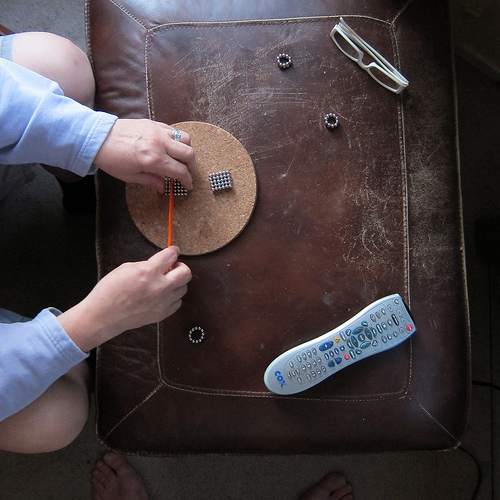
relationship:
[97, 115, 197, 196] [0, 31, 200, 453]
hand on person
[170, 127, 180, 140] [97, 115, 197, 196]
ring on hand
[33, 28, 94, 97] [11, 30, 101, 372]
knee on person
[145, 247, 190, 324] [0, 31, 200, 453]
fingers on person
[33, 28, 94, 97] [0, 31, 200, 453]
knee on person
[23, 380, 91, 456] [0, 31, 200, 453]
knee on person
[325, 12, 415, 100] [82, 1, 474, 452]
glasses on brown table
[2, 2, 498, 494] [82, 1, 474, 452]
floor has brown table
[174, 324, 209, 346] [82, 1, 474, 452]
ring on brown table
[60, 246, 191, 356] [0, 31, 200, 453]
hand on person